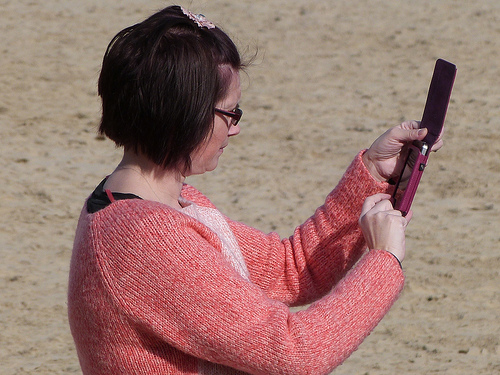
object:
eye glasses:
[210, 106, 244, 126]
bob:
[97, 6, 231, 171]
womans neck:
[117, 148, 191, 198]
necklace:
[111, 158, 173, 205]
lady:
[61, 2, 447, 374]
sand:
[2, 1, 499, 372]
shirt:
[91, 184, 126, 206]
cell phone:
[391, 58, 457, 216]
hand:
[357, 193, 407, 261]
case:
[383, 143, 430, 216]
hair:
[98, 6, 242, 174]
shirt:
[187, 199, 259, 276]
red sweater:
[66, 150, 405, 374]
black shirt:
[87, 177, 145, 213]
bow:
[179, 5, 216, 30]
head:
[93, 7, 243, 173]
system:
[381, 144, 425, 216]